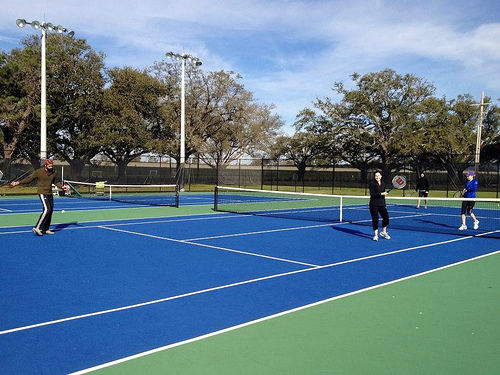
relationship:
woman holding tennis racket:
[363, 170, 392, 244] [387, 169, 411, 196]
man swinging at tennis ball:
[1, 158, 77, 239] [58, 208, 70, 215]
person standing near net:
[454, 170, 483, 236] [214, 183, 500, 237]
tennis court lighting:
[0, 155, 500, 372] [17, 13, 205, 168]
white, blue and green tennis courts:
[3, 228, 360, 293] [0, 155, 500, 372]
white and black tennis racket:
[394, 175, 405, 190] [387, 169, 411, 196]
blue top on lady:
[462, 180, 480, 197] [454, 170, 483, 236]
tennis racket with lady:
[0, 155, 500, 372] [363, 170, 392, 244]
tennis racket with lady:
[387, 169, 411, 196] [363, 170, 392, 244]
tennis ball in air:
[3, 234, 129, 305] [60, 209, 68, 216]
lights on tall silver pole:
[17, 15, 77, 44] [37, 30, 51, 161]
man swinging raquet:
[1, 158, 77, 239] [0, 172, 22, 189]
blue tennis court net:
[3, 234, 129, 305] [214, 183, 500, 237]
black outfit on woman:
[369, 184, 383, 226] [363, 170, 392, 244]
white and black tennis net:
[217, 194, 500, 223] [214, 183, 500, 237]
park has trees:
[3, 2, 497, 372] [1, 30, 498, 203]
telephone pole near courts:
[464, 91, 498, 174] [0, 155, 500, 372]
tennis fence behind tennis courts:
[3, 150, 500, 200] [0, 155, 500, 372]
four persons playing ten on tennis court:
[3, 157, 494, 243] [0, 155, 500, 372]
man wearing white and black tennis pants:
[1, 158, 77, 239] [33, 195, 57, 227]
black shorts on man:
[417, 190, 430, 198] [414, 170, 433, 214]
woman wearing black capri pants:
[454, 170, 483, 236] [462, 200, 478, 216]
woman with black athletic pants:
[363, 170, 392, 244] [369, 205, 390, 228]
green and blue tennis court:
[335, 302, 500, 374] [0, 155, 500, 372]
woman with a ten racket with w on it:
[363, 170, 392, 244] [387, 169, 411, 196]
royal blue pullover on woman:
[462, 180, 480, 197] [454, 170, 483, 236]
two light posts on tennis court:
[17, 13, 205, 168] [0, 155, 500, 372]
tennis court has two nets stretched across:
[0, 155, 500, 372] [58, 176, 499, 238]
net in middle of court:
[190, 130, 496, 228] [5, 15, 498, 371]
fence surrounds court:
[109, 151, 270, 191] [5, 15, 498, 371]